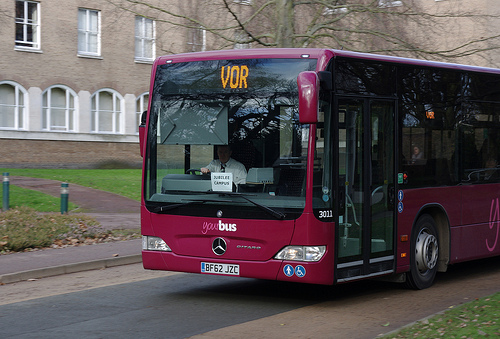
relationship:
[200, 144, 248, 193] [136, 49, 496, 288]
bus driver to bus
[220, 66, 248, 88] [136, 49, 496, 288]
bus sign on bus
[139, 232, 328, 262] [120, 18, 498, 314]
headlights on bus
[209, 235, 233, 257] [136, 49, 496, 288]
logo on front of bus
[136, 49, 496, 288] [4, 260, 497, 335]
bus driving down road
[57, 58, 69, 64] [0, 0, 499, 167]
brick on side of building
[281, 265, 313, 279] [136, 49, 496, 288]
stickers on front of bus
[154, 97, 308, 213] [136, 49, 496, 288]
windshield of bus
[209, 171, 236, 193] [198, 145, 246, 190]
white sign in front of bus driver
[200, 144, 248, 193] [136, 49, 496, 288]
bus driver on side of bus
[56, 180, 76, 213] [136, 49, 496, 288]
green light-post of bus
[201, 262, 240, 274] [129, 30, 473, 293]
license plate in front of bus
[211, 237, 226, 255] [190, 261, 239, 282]
logo above license plate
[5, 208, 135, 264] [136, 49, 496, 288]
leaves are behind bus